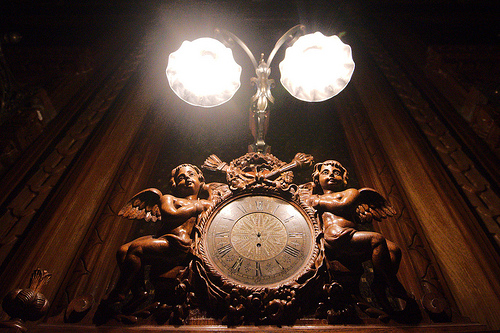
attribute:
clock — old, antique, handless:
[192, 177, 327, 298]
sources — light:
[165, 29, 353, 111]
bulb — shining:
[197, 46, 224, 78]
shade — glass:
[157, 34, 245, 112]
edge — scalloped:
[276, 26, 364, 113]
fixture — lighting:
[145, 16, 367, 209]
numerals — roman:
[216, 199, 304, 280]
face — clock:
[198, 190, 320, 284]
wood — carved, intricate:
[189, 148, 332, 321]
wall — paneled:
[1, 1, 499, 332]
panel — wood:
[0, 1, 499, 332]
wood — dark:
[17, 10, 480, 311]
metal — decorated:
[206, 17, 309, 158]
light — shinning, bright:
[157, 22, 367, 133]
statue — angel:
[108, 153, 216, 314]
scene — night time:
[0, 1, 499, 332]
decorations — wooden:
[86, 140, 425, 331]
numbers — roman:
[205, 197, 320, 294]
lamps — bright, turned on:
[153, 25, 363, 121]